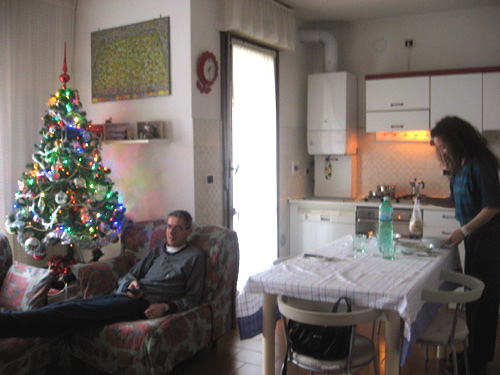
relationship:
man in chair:
[128, 238, 213, 305] [56, 221, 260, 366]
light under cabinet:
[377, 120, 446, 170] [350, 42, 481, 142]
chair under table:
[56, 221, 260, 366] [279, 222, 454, 344]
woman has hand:
[411, 118, 495, 310] [434, 213, 479, 264]